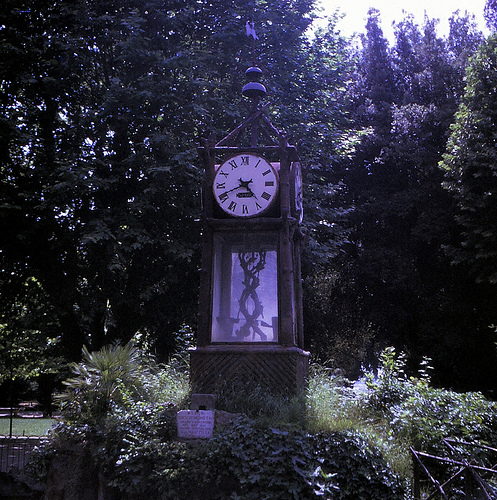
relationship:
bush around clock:
[105, 358, 418, 498] [200, 119, 309, 283]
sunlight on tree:
[292, 2, 493, 63] [293, 2, 363, 268]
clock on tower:
[215, 151, 278, 217] [186, 105, 310, 412]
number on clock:
[237, 156, 251, 165] [210, 149, 278, 218]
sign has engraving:
[159, 391, 248, 470] [177, 408, 218, 432]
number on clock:
[238, 152, 252, 167] [183, 62, 310, 411]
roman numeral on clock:
[226, 199, 236, 209] [183, 62, 310, 411]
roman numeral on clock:
[261, 189, 271, 199] [183, 62, 310, 411]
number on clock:
[216, 167, 232, 181] [183, 62, 310, 411]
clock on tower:
[215, 151, 278, 217] [187, 60, 314, 412]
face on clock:
[212, 153, 279, 218] [183, 62, 310, 411]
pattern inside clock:
[232, 235, 271, 342] [210, 149, 278, 218]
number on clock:
[251, 157, 263, 171] [215, 151, 278, 217]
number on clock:
[255, 165, 272, 183] [200, 143, 303, 233]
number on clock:
[216, 166, 232, 180] [206, 149, 284, 219]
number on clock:
[261, 175, 276, 189] [209, 139, 303, 227]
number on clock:
[215, 192, 230, 203] [213, 152, 280, 215]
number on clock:
[219, 155, 275, 220] [178, 130, 307, 237]